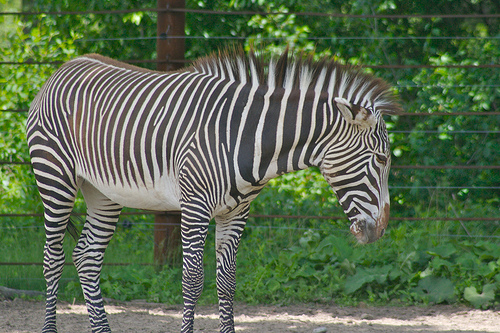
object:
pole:
[62, 53, 183, 86]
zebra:
[23, 47, 405, 333]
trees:
[3, 2, 495, 201]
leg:
[25, 114, 76, 333]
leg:
[72, 184, 123, 319]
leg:
[172, 191, 214, 331]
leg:
[214, 194, 250, 333]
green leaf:
[464, 284, 496, 309]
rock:
[315, 327, 326, 332]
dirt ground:
[1, 297, 499, 330]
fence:
[0, 13, 499, 266]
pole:
[154, 0, 184, 266]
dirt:
[0, 299, 499, 331]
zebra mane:
[180, 41, 404, 115]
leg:
[180, 183, 211, 333]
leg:
[213, 205, 247, 328]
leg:
[72, 188, 124, 325]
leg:
[25, 130, 78, 326]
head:
[320, 98, 390, 244]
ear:
[334, 97, 374, 129]